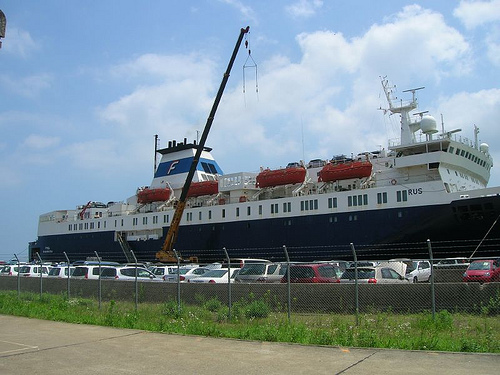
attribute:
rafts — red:
[139, 158, 375, 190]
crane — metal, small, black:
[156, 17, 262, 263]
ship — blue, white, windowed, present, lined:
[26, 140, 497, 253]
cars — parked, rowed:
[2, 254, 489, 288]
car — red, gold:
[280, 260, 335, 281]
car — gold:
[237, 262, 295, 283]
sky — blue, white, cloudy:
[2, 2, 499, 243]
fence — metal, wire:
[9, 241, 499, 314]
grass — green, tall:
[2, 283, 500, 346]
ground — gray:
[2, 313, 496, 374]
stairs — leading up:
[114, 231, 155, 275]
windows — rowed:
[67, 184, 420, 229]